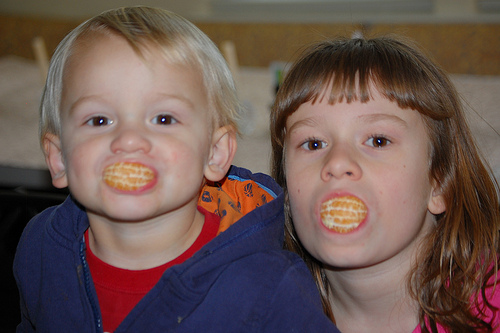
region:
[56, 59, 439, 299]
Two children are seeing front.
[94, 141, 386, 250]
Children are holding orange in mouth.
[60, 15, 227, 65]
Boy hair is blonde color.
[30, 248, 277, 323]
Boy is wearing blue jacket.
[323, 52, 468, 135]
Girl is wearing brown hair.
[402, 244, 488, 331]
Girl is wearing pink dress.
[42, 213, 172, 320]
Boy is wearing red color inner shirt.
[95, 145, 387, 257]
Lips are pink color.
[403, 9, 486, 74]
Wall is brown color.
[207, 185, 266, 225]
Inner lining of the jacket is orange color.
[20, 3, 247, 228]
young boy with blond hair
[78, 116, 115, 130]
eye of young boy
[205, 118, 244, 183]
ear of young boy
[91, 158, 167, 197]
mouth with orange piece in it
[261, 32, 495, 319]
young girl with brown hair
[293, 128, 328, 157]
eye of young girl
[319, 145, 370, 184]
nose of young girl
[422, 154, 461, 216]
ear of young girl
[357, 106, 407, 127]
eyebrow of young girl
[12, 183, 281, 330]
blue jacket on young boy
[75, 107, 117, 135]
the boy's right eye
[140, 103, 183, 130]
the boy's left eye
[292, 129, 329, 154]
the girl's right eye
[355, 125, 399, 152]
the girl's left eye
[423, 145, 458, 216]
the girl's left ear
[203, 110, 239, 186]
the boy's left ear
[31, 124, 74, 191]
the boy's right ear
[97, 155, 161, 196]
an orange in the boy's mouth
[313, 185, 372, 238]
an orange in the girl's mouth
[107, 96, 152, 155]
the nose on the boy's face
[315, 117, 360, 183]
the nose on the girl's face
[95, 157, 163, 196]
the orange in the boy's mouth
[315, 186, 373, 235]
the orange in the girl's face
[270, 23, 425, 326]
this is a girl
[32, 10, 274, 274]
this is a boy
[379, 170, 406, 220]
the girl is light skinned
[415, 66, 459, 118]
this is the hair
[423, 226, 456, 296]
the hair is long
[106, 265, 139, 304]
this is a t shirt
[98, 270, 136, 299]
the t shirt is red in color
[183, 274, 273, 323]
this is a pullover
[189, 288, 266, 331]
the pullover is blue in color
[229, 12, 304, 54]
this is the wall